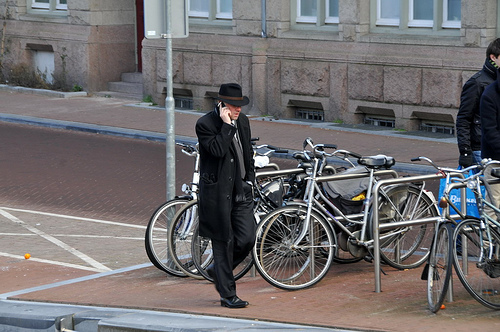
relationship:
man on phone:
[190, 78, 266, 315] [215, 99, 228, 116]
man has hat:
[190, 78, 266, 315] [208, 81, 252, 109]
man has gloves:
[190, 78, 266, 315] [196, 170, 217, 188]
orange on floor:
[437, 301, 444, 312] [1, 202, 497, 331]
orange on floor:
[20, 249, 33, 260] [1, 202, 497, 331]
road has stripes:
[1, 202, 216, 302] [3, 206, 205, 242]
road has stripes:
[1, 202, 216, 302] [1, 209, 113, 273]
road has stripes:
[1, 202, 216, 302] [0, 235, 199, 239]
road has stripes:
[1, 202, 216, 302] [1, 251, 98, 274]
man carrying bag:
[450, 34, 500, 259] [429, 149, 497, 233]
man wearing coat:
[190, 78, 266, 315] [190, 107, 259, 245]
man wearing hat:
[190, 78, 266, 315] [208, 81, 252, 109]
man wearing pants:
[190, 78, 266, 315] [206, 183, 261, 299]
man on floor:
[190, 78, 266, 315] [1, 202, 497, 331]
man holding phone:
[190, 78, 266, 315] [215, 99, 228, 116]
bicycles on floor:
[406, 149, 492, 315] [1, 202, 497, 331]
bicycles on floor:
[444, 163, 500, 316] [1, 202, 497, 331]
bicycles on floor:
[249, 132, 443, 290] [1, 202, 497, 331]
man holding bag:
[450, 34, 500, 259] [429, 149, 497, 233]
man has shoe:
[190, 78, 266, 315] [220, 293, 253, 313]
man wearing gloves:
[450, 34, 500, 259] [456, 151, 478, 170]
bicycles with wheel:
[406, 149, 492, 315] [425, 220, 455, 316]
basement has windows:
[140, 45, 498, 150] [409, 114, 456, 139]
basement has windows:
[140, 45, 498, 150] [352, 107, 396, 133]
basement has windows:
[140, 45, 498, 150] [288, 104, 327, 124]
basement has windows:
[140, 45, 498, 150] [164, 94, 193, 113]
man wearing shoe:
[190, 78, 266, 315] [220, 293, 253, 313]